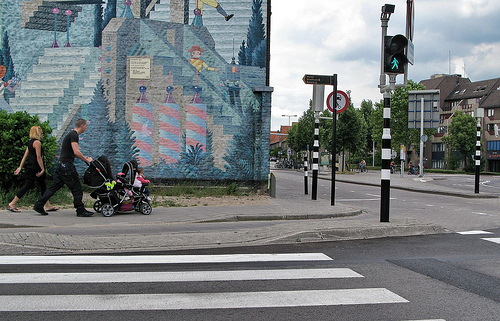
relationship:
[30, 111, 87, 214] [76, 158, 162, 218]
man pushing stroller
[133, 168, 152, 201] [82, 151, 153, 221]
child sitting in stroller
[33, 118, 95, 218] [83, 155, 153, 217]
man pushing baby stroller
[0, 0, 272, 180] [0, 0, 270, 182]
wall mural on wall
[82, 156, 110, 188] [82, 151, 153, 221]
hood on stroller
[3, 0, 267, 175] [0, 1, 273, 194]
mural on building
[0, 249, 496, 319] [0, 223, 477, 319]
road with tarmac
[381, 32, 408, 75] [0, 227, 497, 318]
light beside road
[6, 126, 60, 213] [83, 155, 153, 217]
woman beside baby stroller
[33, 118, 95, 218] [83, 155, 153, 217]
man beside baby stroller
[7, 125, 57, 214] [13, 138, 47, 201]
woman wearing black clothes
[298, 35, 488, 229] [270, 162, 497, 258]
poles on street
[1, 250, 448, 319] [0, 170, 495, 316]
stripes in street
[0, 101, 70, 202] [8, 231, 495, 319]
tree alongside street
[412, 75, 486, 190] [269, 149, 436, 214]
building across street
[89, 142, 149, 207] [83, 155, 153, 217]
child in a baby stroller